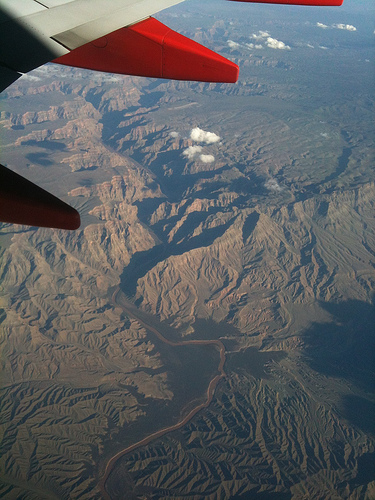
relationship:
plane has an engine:
[0, 3, 342, 230] [60, 19, 239, 85]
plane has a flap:
[0, 3, 342, 230] [52, 15, 146, 52]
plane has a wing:
[0, 3, 342, 230] [2, 4, 191, 92]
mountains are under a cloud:
[2, 1, 375, 500] [184, 123, 223, 166]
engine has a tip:
[60, 19, 239, 85] [197, 46, 238, 83]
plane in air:
[0, 3, 342, 230] [2, 3, 375, 499]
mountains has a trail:
[2, 1, 375, 500] [133, 187, 250, 434]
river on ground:
[105, 324, 226, 467] [0, 3, 374, 499]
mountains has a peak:
[2, 1, 375, 500] [124, 203, 140, 220]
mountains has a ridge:
[2, 1, 375, 500] [139, 196, 163, 253]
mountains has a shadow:
[2, 1, 375, 500] [303, 295, 374, 431]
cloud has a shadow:
[184, 123, 223, 166] [303, 295, 374, 431]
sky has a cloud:
[0, 1, 374, 499] [184, 123, 223, 166]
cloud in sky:
[184, 123, 223, 166] [0, 1, 374, 499]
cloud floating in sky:
[184, 123, 223, 166] [0, 1, 374, 499]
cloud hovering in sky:
[184, 123, 223, 166] [0, 1, 374, 499]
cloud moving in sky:
[184, 123, 223, 166] [0, 1, 374, 499]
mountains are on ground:
[2, 1, 375, 500] [0, 3, 374, 499]